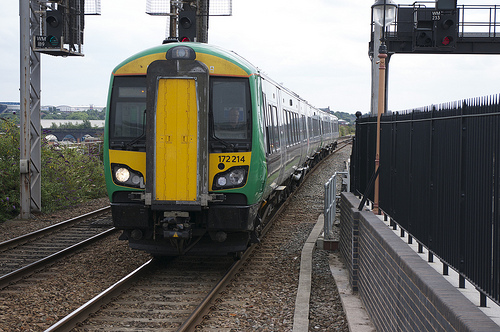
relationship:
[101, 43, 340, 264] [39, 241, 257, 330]
train on track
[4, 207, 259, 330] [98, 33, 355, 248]
track next to train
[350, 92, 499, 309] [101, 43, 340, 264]
fence next to train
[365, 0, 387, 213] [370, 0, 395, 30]
pole has lights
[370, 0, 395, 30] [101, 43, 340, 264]
lights are next to train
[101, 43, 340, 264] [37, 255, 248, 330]
train sitting in track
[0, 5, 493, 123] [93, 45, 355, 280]
sky above train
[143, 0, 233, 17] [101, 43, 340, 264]
lights are above train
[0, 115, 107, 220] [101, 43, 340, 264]
bushes are in left side of train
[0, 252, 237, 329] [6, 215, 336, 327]
two tracks are on ground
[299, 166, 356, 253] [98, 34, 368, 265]
gate next to train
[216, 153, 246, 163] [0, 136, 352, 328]
number on track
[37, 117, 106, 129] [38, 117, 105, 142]
roof on building